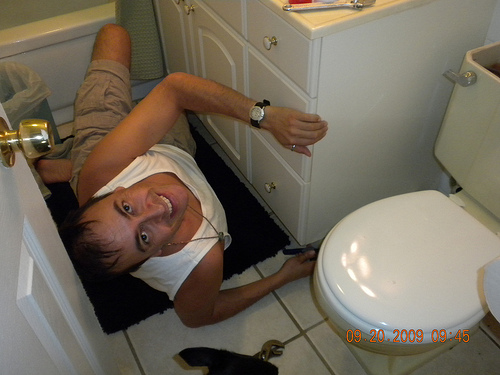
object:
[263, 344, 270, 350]
part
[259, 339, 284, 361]
wrench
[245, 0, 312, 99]
drawer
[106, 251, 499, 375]
bathroom floor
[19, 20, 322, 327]
he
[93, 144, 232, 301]
tank top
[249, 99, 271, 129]
his watch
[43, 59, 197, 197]
cargo pants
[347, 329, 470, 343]
number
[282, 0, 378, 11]
wrench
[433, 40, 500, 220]
tank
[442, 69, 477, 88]
handle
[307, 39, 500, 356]
toilet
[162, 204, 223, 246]
necklace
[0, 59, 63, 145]
trash can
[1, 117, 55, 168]
door knob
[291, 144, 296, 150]
ring